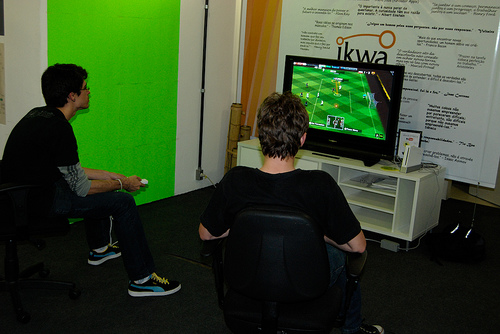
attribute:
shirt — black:
[2, 104, 91, 218]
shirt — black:
[198, 156, 361, 246]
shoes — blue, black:
[85, 243, 182, 297]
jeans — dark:
[53, 183, 156, 280]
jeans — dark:
[328, 245, 365, 333]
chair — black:
[1, 160, 83, 324]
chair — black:
[199, 205, 368, 333]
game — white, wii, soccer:
[398, 144, 422, 173]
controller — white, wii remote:
[139, 177, 149, 186]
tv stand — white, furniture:
[235, 137, 446, 252]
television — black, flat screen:
[282, 54, 405, 165]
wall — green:
[47, 3, 180, 225]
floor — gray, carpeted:
[0, 181, 499, 332]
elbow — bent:
[80, 179, 90, 197]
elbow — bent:
[196, 224, 212, 241]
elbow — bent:
[351, 245, 366, 255]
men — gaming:
[1, 62, 367, 297]